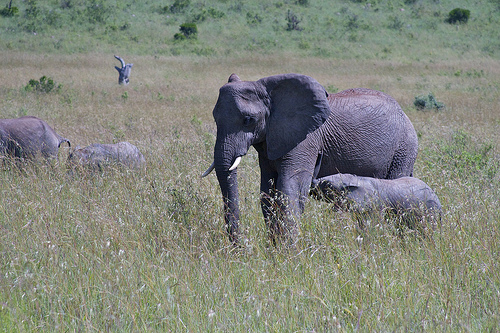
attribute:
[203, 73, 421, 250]
elephant — standing, gray, nursing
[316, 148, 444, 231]
elephant — standing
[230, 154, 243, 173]
tusks — white, ivory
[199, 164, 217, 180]
tusks — white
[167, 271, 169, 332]
grass — long, green, tall, brown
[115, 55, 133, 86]
tree — dead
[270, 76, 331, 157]
ear — large, big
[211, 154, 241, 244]
trunk — long